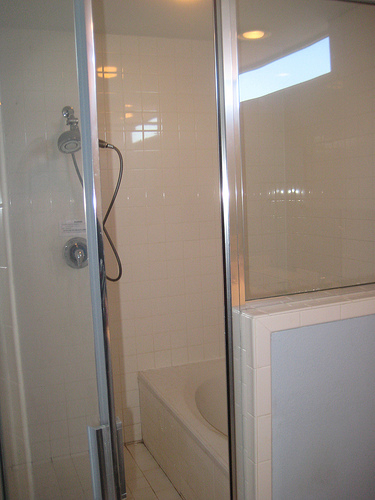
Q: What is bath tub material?
A: Ceramic.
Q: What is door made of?
A: Glass.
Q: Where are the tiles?
A: On wall.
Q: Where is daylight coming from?
A: A window.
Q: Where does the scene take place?
A: In a bathroom.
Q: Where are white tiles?
A: On the walls.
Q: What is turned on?
A: A light.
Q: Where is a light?
A: On the ceiling.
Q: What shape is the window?
A: Rectangular.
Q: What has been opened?
A: A glass door.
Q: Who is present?
A: Nobody.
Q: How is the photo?
A: Clear.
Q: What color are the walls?
A: White.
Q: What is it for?
A: Showering.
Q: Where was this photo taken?
A: In a shower.